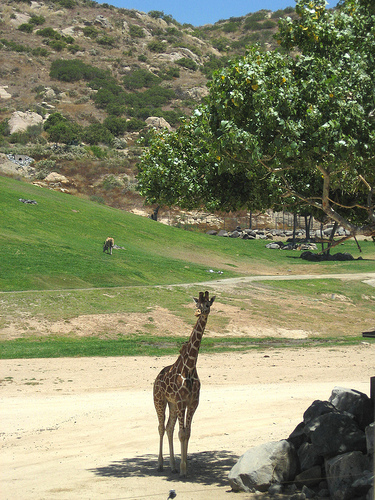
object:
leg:
[153, 395, 167, 471]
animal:
[103, 237, 114, 255]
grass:
[212, 236, 283, 253]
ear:
[193, 297, 198, 302]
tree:
[134, 0, 375, 255]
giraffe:
[153, 288, 217, 477]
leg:
[166, 411, 178, 473]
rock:
[303, 400, 353, 446]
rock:
[266, 241, 284, 249]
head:
[193, 291, 216, 317]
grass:
[0, 228, 54, 281]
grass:
[13, 205, 61, 252]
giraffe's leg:
[177, 417, 186, 478]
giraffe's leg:
[185, 413, 192, 453]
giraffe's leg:
[166, 412, 177, 474]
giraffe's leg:
[157, 416, 165, 472]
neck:
[189, 323, 202, 344]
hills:
[0, 0, 375, 238]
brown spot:
[175, 375, 183, 389]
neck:
[176, 342, 198, 365]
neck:
[182, 331, 200, 349]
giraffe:
[151, 288, 224, 456]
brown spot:
[196, 324, 202, 332]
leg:
[186, 404, 201, 460]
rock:
[7, 109, 43, 134]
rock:
[145, 117, 171, 130]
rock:
[188, 85, 206, 91]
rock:
[173, 48, 198, 60]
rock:
[93, 15, 109, 28]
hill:
[0, 0, 198, 195]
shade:
[86, 449, 241, 487]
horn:
[204, 291, 209, 301]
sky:
[161, 0, 230, 14]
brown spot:
[181, 365, 188, 378]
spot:
[187, 343, 192, 353]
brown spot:
[173, 384, 177, 392]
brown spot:
[169, 376, 174, 383]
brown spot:
[188, 348, 196, 357]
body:
[153, 366, 201, 412]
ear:
[210, 296, 217, 306]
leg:
[176, 406, 187, 479]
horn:
[199, 292, 204, 299]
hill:
[0, 172, 375, 359]